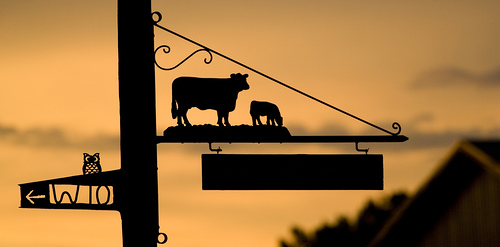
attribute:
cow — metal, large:
[170, 73, 250, 126]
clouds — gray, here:
[405, 65, 499, 96]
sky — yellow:
[2, 3, 496, 246]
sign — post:
[19, 0, 408, 246]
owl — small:
[82, 152, 102, 174]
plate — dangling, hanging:
[201, 142, 384, 192]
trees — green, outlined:
[277, 193, 402, 244]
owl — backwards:
[53, 183, 111, 203]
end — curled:
[388, 120, 406, 136]